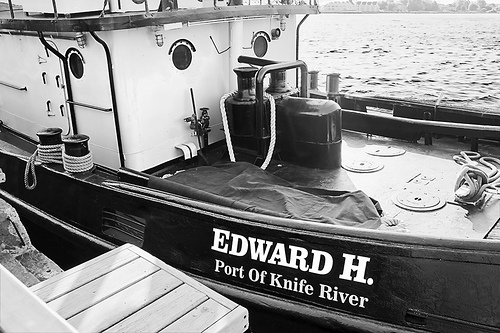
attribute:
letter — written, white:
[338, 251, 369, 284]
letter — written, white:
[310, 245, 334, 278]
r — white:
[287, 245, 312, 271]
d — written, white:
[227, 233, 252, 265]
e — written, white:
[208, 219, 235, 255]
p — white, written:
[211, 256, 224, 275]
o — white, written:
[224, 264, 233, 276]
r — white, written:
[232, 269, 242, 280]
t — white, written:
[239, 267, 247, 282]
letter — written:
[296, 272, 309, 294]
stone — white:
[30, 237, 252, 332]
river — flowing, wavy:
[297, 11, 499, 105]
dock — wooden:
[5, 205, 269, 332]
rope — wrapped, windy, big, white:
[19, 141, 93, 180]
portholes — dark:
[55, 34, 269, 82]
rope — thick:
[221, 84, 280, 165]